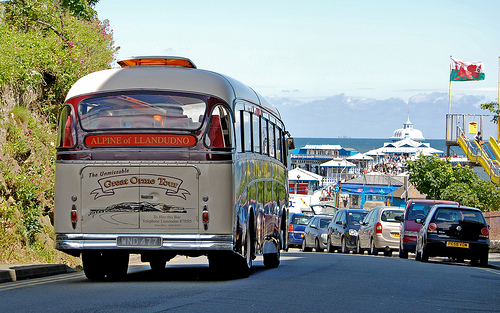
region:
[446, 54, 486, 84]
a white, green, and red flag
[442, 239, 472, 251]
a yellow license plate on a car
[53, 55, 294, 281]
a bus on a road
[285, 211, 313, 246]
a blue vehicle parked alongside a road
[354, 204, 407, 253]
a gray minivan parked alongside a road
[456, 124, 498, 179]
a yellow lined stair rail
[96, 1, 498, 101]
a pale blue sky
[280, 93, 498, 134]
mountains in the distance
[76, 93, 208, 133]
the rear window of a bus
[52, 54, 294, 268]
an old beige buse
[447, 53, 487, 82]
a green, red and white flag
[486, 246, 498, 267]
part of a sidewalk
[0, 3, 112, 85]
a wall of green trees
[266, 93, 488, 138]
part of a mountain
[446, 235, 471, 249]
a yellow license plate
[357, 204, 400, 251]
part of a gray car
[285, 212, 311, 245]
part of a blue car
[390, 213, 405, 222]
a vehicle's side mirror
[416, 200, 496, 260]
car on a street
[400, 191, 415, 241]
car on a street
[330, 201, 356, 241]
car on a street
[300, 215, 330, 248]
car on a street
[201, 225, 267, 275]
tire on a bus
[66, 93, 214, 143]
window on a bus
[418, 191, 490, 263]
Black car parked on the street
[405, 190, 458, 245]
red truck parked on the street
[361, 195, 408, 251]
silver car parked on the street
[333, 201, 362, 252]
black car parked on the street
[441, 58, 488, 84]
flag on the pole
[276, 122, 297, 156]
mirror on the bus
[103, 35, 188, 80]
vent on top of a bus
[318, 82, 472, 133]
mountains in the distance view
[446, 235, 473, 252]
license plate on a car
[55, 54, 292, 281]
a white bus on road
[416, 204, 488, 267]
a parked black car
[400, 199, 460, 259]
a parked red van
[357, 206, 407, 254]
a parked silver van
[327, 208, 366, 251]
a parked black car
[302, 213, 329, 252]
a parked silver car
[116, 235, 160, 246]
a grey and white license plate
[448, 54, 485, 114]
a waving flag on pole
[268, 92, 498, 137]
a mountain range in distance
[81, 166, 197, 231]
a painted bus advertisement